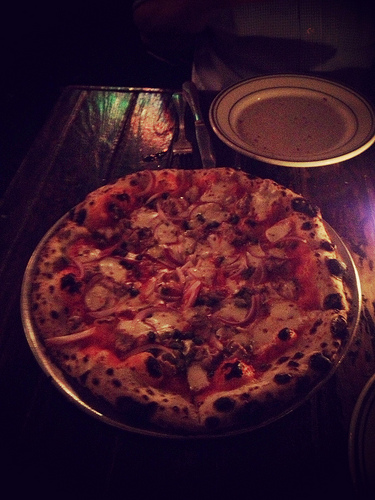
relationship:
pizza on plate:
[17, 163, 357, 442] [202, 68, 373, 174]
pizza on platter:
[17, 163, 357, 442] [14, 208, 371, 447]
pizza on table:
[17, 163, 357, 442] [1, 77, 370, 484]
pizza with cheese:
[17, 163, 357, 442] [80, 292, 128, 311]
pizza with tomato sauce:
[17, 163, 357, 442] [82, 325, 134, 359]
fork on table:
[166, 90, 197, 160] [1, 77, 370, 484]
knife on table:
[181, 77, 219, 171] [1, 77, 370, 484]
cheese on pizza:
[80, 292, 128, 311] [17, 163, 357, 442]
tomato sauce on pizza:
[82, 325, 134, 359] [17, 163, 357, 442]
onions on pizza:
[241, 247, 267, 325] [17, 163, 357, 442]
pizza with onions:
[17, 163, 357, 442] [241, 247, 267, 325]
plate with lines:
[202, 68, 373, 174] [208, 101, 224, 131]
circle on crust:
[209, 393, 236, 416] [194, 339, 336, 428]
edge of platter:
[19, 332, 108, 418] [14, 208, 371, 447]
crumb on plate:
[254, 130, 269, 146] [202, 68, 373, 174]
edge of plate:
[209, 116, 225, 134] [202, 68, 373, 174]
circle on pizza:
[209, 393, 236, 416] [17, 163, 357, 442]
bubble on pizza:
[122, 345, 171, 386] [17, 163, 357, 442]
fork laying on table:
[166, 90, 197, 160] [1, 77, 370, 484]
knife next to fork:
[181, 77, 219, 171] [166, 90, 197, 160]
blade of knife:
[194, 124, 214, 172] [181, 77, 219, 171]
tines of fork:
[169, 147, 199, 165] [166, 90, 197, 160]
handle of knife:
[182, 80, 204, 120] [181, 77, 219, 171]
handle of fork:
[170, 93, 189, 128] [166, 90, 197, 160]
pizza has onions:
[17, 163, 357, 442] [241, 247, 267, 325]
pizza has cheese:
[17, 163, 357, 442] [80, 292, 128, 311]